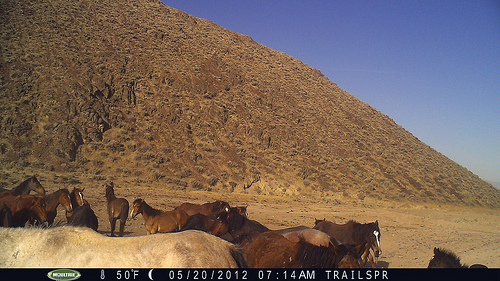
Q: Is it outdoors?
A: Yes, it is outdoors.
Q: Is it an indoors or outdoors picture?
A: It is outdoors.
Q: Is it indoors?
A: No, it is outdoors.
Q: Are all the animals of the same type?
A: Yes, all the animals are horses.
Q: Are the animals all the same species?
A: Yes, all the animals are horses.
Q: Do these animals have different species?
A: No, all the animals are horses.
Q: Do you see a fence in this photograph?
A: No, there are no fences.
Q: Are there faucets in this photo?
A: No, there are no faucets.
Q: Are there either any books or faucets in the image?
A: No, there are no faucets or books.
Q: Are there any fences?
A: No, there are no fences.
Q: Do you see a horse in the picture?
A: Yes, there is a horse.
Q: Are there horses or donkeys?
A: Yes, there is a horse.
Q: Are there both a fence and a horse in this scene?
A: No, there is a horse but no fences.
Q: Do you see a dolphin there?
A: No, there are no dolphins.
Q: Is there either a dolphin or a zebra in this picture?
A: No, there are no dolphins or zebras.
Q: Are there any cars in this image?
A: No, there are no cars.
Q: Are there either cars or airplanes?
A: No, there are no cars or airplanes.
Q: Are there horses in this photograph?
A: Yes, there is a horse.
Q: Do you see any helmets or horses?
A: Yes, there is a horse.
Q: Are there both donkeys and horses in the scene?
A: No, there is a horse but no donkeys.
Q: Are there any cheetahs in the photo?
A: No, there are no cheetahs.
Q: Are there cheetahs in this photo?
A: No, there are no cheetahs.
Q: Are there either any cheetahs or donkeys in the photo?
A: No, there are no cheetahs or donkeys.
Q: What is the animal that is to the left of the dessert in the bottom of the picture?
A: The animal is a horse.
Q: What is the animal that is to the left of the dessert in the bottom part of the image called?
A: The animal is a horse.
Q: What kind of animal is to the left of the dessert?
A: The animal is a horse.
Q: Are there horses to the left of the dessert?
A: Yes, there is a horse to the left of the dessert.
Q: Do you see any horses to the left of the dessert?
A: Yes, there is a horse to the left of the dessert.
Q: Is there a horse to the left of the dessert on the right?
A: Yes, there is a horse to the left of the dessert.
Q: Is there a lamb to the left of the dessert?
A: No, there is a horse to the left of the dessert.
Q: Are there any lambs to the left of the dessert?
A: No, there is a horse to the left of the dessert.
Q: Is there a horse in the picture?
A: Yes, there is a horse.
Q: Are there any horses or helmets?
A: Yes, there is a horse.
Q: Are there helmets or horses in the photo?
A: Yes, there is a horse.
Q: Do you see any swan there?
A: No, there are no swans.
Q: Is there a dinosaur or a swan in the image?
A: No, there are no swans or dinosaurs.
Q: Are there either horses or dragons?
A: Yes, there is a horse.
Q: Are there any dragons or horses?
A: Yes, there is a horse.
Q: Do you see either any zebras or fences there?
A: No, there are no fences or zebras.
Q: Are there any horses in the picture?
A: Yes, there is a horse.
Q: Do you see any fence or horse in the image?
A: Yes, there is a horse.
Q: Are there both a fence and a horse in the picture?
A: No, there is a horse but no fences.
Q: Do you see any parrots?
A: No, there are no parrots.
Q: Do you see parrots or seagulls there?
A: No, there are no parrots or seagulls.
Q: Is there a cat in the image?
A: No, there are no cats.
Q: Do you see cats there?
A: No, there are no cats.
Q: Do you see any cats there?
A: No, there are no cats.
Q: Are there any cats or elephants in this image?
A: No, there are no cats or elephants.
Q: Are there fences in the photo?
A: No, there are no fences.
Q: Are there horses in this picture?
A: Yes, there is a horse.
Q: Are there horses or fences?
A: Yes, there is a horse.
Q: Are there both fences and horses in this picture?
A: No, there is a horse but no fences.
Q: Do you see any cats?
A: No, there are no cats.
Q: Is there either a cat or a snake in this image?
A: No, there are no cats or snakes.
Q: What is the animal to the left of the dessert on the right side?
A: The animal is a horse.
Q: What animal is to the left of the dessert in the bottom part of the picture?
A: The animal is a horse.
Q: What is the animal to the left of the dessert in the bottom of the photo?
A: The animal is a horse.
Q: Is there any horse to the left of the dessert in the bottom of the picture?
A: Yes, there is a horse to the left of the dessert.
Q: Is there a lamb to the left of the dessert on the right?
A: No, there is a horse to the left of the dessert.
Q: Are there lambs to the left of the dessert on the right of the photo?
A: No, there is a horse to the left of the dessert.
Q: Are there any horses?
A: Yes, there is a horse.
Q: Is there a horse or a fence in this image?
A: Yes, there is a horse.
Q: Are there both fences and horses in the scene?
A: No, there is a horse but no fences.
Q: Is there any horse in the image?
A: Yes, there is a horse.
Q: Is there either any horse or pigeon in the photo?
A: Yes, there is a horse.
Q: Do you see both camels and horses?
A: No, there is a horse but no camels.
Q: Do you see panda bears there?
A: No, there are no panda bears.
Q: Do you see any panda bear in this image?
A: No, there are no panda bears.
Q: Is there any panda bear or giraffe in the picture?
A: No, there are no panda bears or giraffes.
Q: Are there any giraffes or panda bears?
A: No, there are no panda bears or giraffes.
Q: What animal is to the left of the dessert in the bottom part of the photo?
A: The animal is a horse.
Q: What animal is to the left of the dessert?
A: The animal is a horse.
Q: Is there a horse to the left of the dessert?
A: Yes, there is a horse to the left of the dessert.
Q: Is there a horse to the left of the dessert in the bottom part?
A: Yes, there is a horse to the left of the dessert.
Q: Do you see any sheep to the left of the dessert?
A: No, there is a horse to the left of the dessert.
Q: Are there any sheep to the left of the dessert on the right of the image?
A: No, there is a horse to the left of the dessert.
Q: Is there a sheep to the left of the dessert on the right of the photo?
A: No, there is a horse to the left of the dessert.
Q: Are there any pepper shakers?
A: No, there are no pepper shakers.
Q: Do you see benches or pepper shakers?
A: No, there are no pepper shakers or benches.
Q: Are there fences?
A: No, there are no fences.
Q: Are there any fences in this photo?
A: No, there are no fences.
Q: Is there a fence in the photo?
A: No, there are no fences.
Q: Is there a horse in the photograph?
A: Yes, there is a horse.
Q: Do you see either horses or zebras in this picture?
A: Yes, there is a horse.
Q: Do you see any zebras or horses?
A: Yes, there is a horse.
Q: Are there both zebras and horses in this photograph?
A: No, there is a horse but no zebras.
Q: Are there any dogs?
A: No, there are no dogs.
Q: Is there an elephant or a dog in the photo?
A: No, there are no dogs or elephants.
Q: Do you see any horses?
A: Yes, there is a horse.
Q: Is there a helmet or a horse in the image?
A: Yes, there is a horse.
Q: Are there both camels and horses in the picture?
A: No, there is a horse but no camels.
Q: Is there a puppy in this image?
A: No, there are no puppies.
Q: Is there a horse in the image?
A: Yes, there is a horse.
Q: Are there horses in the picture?
A: Yes, there is a horse.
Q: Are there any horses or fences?
A: Yes, there is a horse.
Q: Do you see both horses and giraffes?
A: No, there is a horse but no giraffes.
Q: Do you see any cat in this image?
A: No, there are no cats.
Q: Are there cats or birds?
A: No, there are no cats or birds.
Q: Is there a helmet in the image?
A: No, there are no helmets.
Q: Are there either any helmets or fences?
A: No, there are no helmets or fences.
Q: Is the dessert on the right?
A: Yes, the dessert is on the right of the image.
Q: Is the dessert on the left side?
A: No, the dessert is on the right of the image.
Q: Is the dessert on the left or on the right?
A: The dessert is on the right of the image.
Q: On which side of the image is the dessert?
A: The dessert is on the right of the image.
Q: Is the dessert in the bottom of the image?
A: Yes, the dessert is in the bottom of the image.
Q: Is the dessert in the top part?
A: No, the dessert is in the bottom of the image.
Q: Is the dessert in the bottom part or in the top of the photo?
A: The dessert is in the bottom of the image.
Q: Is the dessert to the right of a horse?
A: Yes, the dessert is to the right of a horse.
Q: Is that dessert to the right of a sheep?
A: No, the dessert is to the right of a horse.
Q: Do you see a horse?
A: Yes, there is a horse.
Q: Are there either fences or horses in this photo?
A: Yes, there is a horse.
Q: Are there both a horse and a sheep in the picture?
A: No, there is a horse but no sheep.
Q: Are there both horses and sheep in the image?
A: No, there is a horse but no sheep.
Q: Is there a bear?
A: No, there are no bears.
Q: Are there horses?
A: Yes, there is a horse.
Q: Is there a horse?
A: Yes, there is a horse.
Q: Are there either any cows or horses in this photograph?
A: Yes, there is a horse.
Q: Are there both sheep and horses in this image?
A: No, there is a horse but no sheep.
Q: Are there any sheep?
A: No, there are no sheep.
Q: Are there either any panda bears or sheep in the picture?
A: No, there are no sheep or panda bears.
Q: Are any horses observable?
A: Yes, there is a horse.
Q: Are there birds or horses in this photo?
A: Yes, there is a horse.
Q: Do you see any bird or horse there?
A: Yes, there is a horse.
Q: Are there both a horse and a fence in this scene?
A: No, there is a horse but no fences.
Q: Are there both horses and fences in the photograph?
A: No, there is a horse but no fences.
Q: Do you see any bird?
A: No, there are no birds.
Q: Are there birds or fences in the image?
A: No, there are no birds or fences.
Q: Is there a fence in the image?
A: No, there are no fences.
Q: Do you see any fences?
A: No, there are no fences.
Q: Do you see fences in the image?
A: No, there are no fences.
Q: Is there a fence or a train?
A: No, there are no fences or trains.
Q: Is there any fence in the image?
A: No, there are no fences.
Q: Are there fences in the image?
A: No, there are no fences.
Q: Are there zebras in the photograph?
A: No, there are no zebras.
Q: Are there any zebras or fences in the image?
A: No, there are no zebras or fences.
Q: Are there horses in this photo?
A: Yes, there is a horse.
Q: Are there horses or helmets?
A: Yes, there is a horse.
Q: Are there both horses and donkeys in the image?
A: No, there is a horse but no donkeys.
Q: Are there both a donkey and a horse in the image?
A: No, there is a horse but no donkeys.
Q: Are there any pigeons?
A: No, there are no pigeons.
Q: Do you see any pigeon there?
A: No, there are no pigeons.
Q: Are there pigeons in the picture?
A: No, there are no pigeons.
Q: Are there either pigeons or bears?
A: No, there are no pigeons or bears.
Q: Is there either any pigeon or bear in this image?
A: No, there are no pigeons or bears.